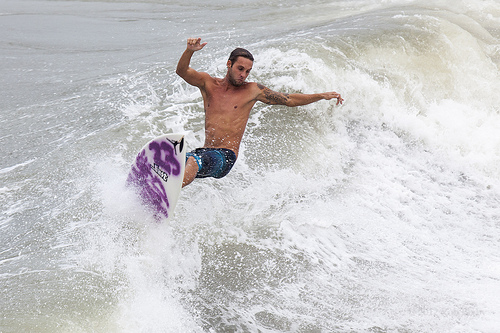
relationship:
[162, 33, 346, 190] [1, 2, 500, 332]
man surfing in water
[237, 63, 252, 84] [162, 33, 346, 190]
face of man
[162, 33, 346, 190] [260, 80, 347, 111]
man with arm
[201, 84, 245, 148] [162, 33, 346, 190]
chest of man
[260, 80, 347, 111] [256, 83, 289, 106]
arm has a tattoo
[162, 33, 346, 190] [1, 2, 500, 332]
man in water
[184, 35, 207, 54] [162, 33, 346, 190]
hand of man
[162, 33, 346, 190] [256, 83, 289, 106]
man with tattoo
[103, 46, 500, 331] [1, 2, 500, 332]
wave across water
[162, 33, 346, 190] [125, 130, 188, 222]
man riding surfboard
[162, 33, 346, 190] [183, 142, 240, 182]
man wearing shorts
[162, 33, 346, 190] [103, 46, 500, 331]
man riding wave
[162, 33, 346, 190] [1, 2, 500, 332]
man on top of water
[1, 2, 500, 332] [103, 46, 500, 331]
water with wave